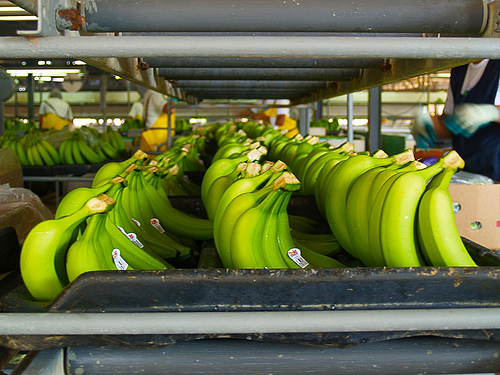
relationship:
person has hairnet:
[38, 88, 74, 131] [45, 90, 68, 100]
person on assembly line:
[409, 58, 499, 182] [9, 89, 495, 267]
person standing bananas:
[409, 58, 499, 182] [206, 171, 312, 272]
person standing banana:
[409, 58, 499, 182] [66, 195, 104, 282]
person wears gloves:
[410, 59, 495, 173] [459, 98, 488, 132]